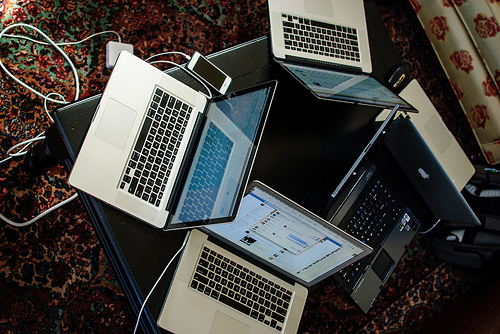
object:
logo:
[418, 165, 430, 180]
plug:
[177, 50, 191, 61]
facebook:
[203, 186, 364, 283]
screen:
[214, 180, 372, 288]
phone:
[185, 49, 232, 95]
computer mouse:
[386, 64, 409, 90]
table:
[0, 0, 500, 334]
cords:
[0, 17, 122, 227]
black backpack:
[430, 161, 499, 268]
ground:
[2, 238, 100, 328]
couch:
[411, 0, 500, 165]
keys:
[117, 85, 193, 211]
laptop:
[68, 50, 279, 232]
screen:
[166, 86, 271, 225]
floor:
[171, 17, 211, 38]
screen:
[371, 114, 481, 230]